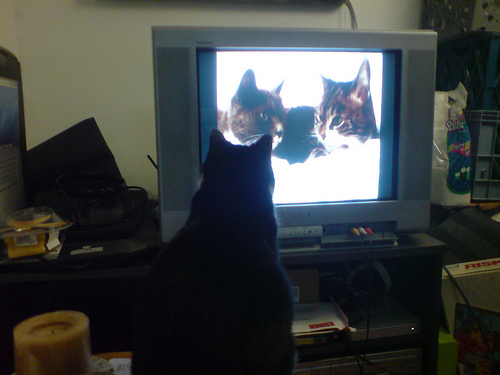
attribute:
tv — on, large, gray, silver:
[152, 25, 431, 237]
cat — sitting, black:
[134, 127, 301, 373]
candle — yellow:
[6, 309, 99, 373]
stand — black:
[5, 234, 447, 374]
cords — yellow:
[338, 219, 395, 304]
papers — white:
[282, 293, 357, 341]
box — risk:
[432, 244, 499, 326]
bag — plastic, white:
[426, 84, 478, 211]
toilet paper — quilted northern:
[436, 110, 467, 161]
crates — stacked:
[423, 1, 499, 209]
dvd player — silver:
[336, 283, 419, 345]